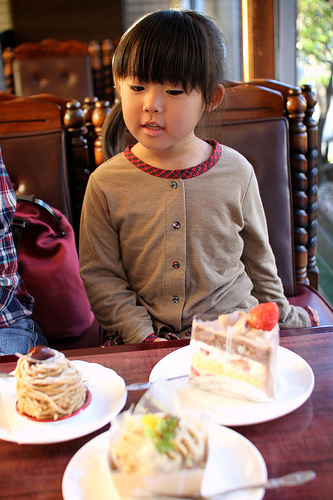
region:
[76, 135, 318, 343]
button down tan sweater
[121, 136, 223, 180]
plaid trim on boat shaped collar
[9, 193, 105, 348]
canvas bag with wooden handles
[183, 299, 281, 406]
wax paper wrapped piece of cake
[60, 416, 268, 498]
white ceramic plate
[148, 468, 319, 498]
fork on plate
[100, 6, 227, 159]
girl's hair in ponytail and bangs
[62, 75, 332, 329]
burgundy leather upholstered chair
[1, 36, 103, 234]
two empty chairs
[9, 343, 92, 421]
noodle wrapped plum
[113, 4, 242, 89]
Her hair is dark.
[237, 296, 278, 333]
The strawberry is red.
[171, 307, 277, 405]
The cake is on the plate.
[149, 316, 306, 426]
The plate is white.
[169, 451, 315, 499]
The spoon is on the plate.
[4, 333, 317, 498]
Three plates are on the table.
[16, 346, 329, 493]
The table is brown.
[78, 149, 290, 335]
Her shirt is tan.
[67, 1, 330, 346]
The girl is young.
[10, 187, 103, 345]
The purse is maroon.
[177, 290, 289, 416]
a slice of cake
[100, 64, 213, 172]
girl is looking at the cake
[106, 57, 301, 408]
girl is looking at the cake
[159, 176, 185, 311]
Four round buttons on a sweater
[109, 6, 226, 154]
The girl has black hair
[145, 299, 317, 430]
A cake on the plate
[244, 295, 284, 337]
A strawberry is red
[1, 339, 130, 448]
Pastry on a plate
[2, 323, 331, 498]
A brown wooden table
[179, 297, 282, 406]
The cake is triangular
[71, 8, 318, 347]
Little girl sitting on a chair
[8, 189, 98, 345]
A bag is colored red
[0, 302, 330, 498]
Three plates on a table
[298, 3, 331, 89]
a tree out the door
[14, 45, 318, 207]
three brown chairs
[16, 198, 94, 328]
a red bag on a chair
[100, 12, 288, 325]
a girl wearing a brown shirt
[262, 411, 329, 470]
a wooden table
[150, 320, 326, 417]
cake on a plate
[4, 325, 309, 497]
plates of cake on a table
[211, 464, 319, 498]
the handle of a fork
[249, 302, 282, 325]
a strawberry on the cake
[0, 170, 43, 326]
a person wearing a plaid shirt